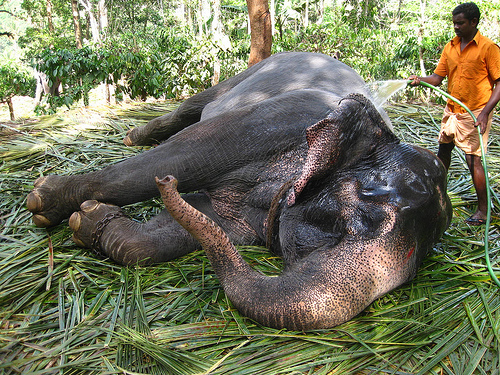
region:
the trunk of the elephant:
[151, 171, 420, 328]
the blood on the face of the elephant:
[398, 238, 418, 267]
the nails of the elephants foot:
[23, 175, 60, 232]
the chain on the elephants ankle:
[87, 208, 134, 260]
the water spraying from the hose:
[353, 70, 408, 107]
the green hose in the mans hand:
[406, 71, 432, 90]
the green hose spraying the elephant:
[406, 72, 499, 312]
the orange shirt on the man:
[436, 33, 498, 113]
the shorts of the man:
[439, 105, 486, 153]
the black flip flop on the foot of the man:
[463, 208, 491, 231]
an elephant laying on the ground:
[43, 53, 445, 324]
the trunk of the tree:
[246, 3, 271, 73]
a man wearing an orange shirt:
[423, 18, 498, 191]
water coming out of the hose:
[361, 73, 400, 108]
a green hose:
[408, 80, 498, 283]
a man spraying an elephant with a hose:
[324, 17, 496, 211]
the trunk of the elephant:
[158, 177, 405, 329]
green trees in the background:
[22, 20, 207, 100]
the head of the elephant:
[271, 90, 442, 313]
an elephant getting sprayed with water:
[58, 55, 468, 300]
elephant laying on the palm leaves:
[26, 51, 451, 328]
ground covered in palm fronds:
[4, 118, 498, 370]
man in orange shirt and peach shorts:
[412, 5, 499, 220]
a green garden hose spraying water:
[405, 78, 499, 284]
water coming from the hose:
[344, 76, 406, 108]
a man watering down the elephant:
[368, 4, 495, 221]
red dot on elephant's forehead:
[404, 244, 413, 264]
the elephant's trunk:
[153, 175, 354, 329]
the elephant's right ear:
[288, 94, 398, 198]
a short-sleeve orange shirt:
[434, 35, 499, 109]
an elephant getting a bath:
[22, 0, 492, 326]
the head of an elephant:
[276, 93, 458, 330]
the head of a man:
[448, 3, 482, 42]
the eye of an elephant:
[357, 203, 376, 231]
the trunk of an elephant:
[153, 169, 337, 349]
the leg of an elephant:
[117, 99, 201, 142]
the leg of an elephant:
[68, 189, 160, 270]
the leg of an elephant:
[20, 157, 151, 226]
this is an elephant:
[255, 94, 455, 281]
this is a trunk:
[257, 228, 377, 364]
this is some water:
[362, 81, 430, 140]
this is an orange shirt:
[405, 51, 496, 74]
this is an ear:
[300, 162, 382, 194]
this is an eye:
[359, 187, 418, 220]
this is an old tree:
[39, 76, 131, 105]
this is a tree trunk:
[171, 21, 362, 118]